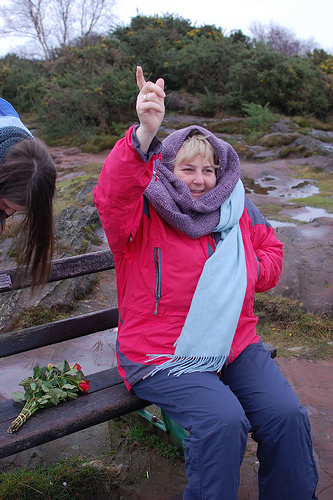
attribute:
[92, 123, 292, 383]
jacket — pink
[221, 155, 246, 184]
scarf — purple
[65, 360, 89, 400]
flowers — red